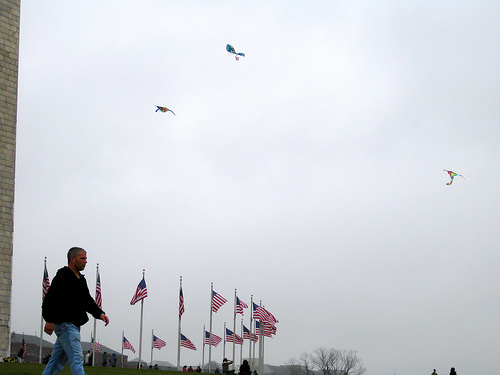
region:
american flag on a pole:
[42, 257, 49, 369]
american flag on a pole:
[130, 268, 146, 370]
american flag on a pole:
[177, 274, 186, 374]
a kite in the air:
[223, 43, 244, 60]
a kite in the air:
[153, 107, 173, 116]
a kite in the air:
[440, 168, 461, 187]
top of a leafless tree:
[288, 346, 364, 373]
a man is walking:
[43, 247, 109, 374]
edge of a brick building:
[0, 3, 22, 369]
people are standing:
[428, 366, 460, 373]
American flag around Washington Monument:
[28, 258, 58, 353]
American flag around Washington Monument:
[87, 267, 110, 327]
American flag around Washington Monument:
[135, 256, 144, 309]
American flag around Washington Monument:
[175, 281, 187, 310]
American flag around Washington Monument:
[87, 337, 104, 354]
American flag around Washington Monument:
[117, 330, 134, 352]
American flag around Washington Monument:
[151, 330, 165, 352]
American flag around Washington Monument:
[176, 327, 196, 348]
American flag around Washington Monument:
[200, 326, 220, 341]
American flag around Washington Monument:
[223, 331, 246, 351]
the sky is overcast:
[89, 36, 476, 275]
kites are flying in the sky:
[117, 20, 468, 215]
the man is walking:
[27, 231, 129, 366]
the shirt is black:
[20, 263, 108, 328]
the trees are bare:
[265, 335, 367, 371]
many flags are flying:
[40, 248, 296, 365]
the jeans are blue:
[32, 315, 97, 367]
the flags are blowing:
[192, 277, 285, 347]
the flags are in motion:
[112, 274, 262, 354]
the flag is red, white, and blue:
[177, 272, 239, 317]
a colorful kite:
[225, 38, 252, 63]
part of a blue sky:
[410, 28, 495, 76]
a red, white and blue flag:
[127, 277, 149, 306]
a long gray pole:
[136, 298, 146, 365]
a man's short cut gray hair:
[66, 246, 83, 261]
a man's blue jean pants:
[38, 317, 92, 374]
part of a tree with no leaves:
[291, 342, 364, 374]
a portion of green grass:
[81, 361, 126, 373]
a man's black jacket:
[42, 266, 103, 329]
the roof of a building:
[7, 328, 52, 347]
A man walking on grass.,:
[35, 238, 104, 370]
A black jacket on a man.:
[44, 264, 103, 331]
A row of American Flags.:
[42, 258, 274, 373]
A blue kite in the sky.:
[223, 41, 245, 58]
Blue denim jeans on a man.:
[40, 320, 90, 371]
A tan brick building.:
[1, 2, 18, 366]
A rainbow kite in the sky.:
[440, 168, 462, 184]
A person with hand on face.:
[218, 357, 234, 372]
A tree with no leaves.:
[275, 346, 367, 373]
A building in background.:
[14, 331, 131, 366]